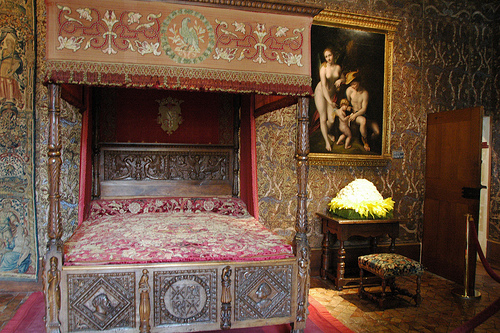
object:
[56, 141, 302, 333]
bed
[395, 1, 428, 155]
wallpaper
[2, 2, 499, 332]
bedroom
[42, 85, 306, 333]
frame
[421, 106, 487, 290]
door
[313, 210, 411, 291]
table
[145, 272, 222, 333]
emblem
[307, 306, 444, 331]
floor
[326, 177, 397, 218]
arrangement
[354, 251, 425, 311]
stool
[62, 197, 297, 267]
bedspread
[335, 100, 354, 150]
person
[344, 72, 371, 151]
person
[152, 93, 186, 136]
decoration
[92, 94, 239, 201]
headboard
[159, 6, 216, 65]
circle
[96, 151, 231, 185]
carving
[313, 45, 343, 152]
lady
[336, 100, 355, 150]
child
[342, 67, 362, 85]
hat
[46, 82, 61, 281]
posts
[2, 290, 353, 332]
rug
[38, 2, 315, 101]
canopy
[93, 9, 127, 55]
design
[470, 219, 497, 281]
rope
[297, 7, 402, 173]
frame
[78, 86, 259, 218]
curtains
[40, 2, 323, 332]
bed